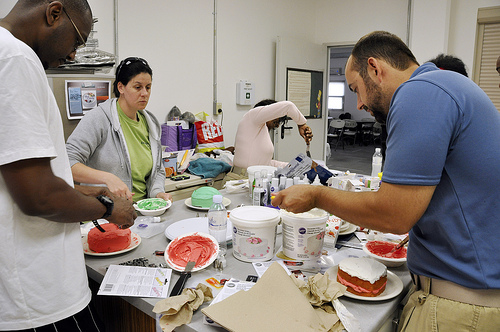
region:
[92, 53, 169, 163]
this is a lady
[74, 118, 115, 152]
this is a jacket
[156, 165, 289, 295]
the table is full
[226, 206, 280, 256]
this is a container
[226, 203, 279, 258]
the container is white in color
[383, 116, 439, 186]
this is the hand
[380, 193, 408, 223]
the man is light skinned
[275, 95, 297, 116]
the elbow is bent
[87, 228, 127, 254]
this is a cake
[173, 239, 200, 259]
the cream is red in color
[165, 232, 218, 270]
A plate with frosting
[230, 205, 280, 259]
A white bucket of frosting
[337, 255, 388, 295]
A white frosted cake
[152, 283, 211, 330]
A tan colored napkin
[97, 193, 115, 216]
A watch being worn on a wrist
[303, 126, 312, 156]
A knife used for decorating cakes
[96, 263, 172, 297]
A white piece of paper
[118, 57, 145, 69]
Glasses worn on a lady's head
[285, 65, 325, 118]
A bulletin board on a wall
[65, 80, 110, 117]
A small poster hanging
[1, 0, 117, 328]
man in a white shirt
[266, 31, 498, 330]
man in a blue shirt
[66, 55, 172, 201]
woman in a gray jacket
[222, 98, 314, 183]
woman in a pink shirt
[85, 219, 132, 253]
cake with pink icing on it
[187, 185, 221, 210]
cake with green icing on it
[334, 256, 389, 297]
cake with white icing on top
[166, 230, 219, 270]
bowl with pink icing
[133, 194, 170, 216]
bowl with green icing in it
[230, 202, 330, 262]
buckets of icing in them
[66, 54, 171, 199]
A woman wearing green and gray.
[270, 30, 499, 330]
A man in a blue shirt.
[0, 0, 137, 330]
A man wearing a white shirt.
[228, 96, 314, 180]
A woman wearing a pink shirt.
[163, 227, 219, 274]
A bowl of frosting.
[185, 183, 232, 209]
A green frosted cake.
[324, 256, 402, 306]
A white and red cake.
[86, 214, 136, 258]
A red frosted cake.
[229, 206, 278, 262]
A bucket of cake frosting.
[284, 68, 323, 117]
A bulletin board on a wall.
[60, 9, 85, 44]
The ear handles of glasses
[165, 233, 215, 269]
Cake frosting on a plate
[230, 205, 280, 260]
A bucket of frosting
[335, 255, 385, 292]
A cake with frosting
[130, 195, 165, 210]
A bowl with green frosting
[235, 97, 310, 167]
A woman putting frosting on a cake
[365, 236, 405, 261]
A bowl of red frosting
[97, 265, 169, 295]
A piece of paper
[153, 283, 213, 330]
A tan napkin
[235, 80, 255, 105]
A box with green on it